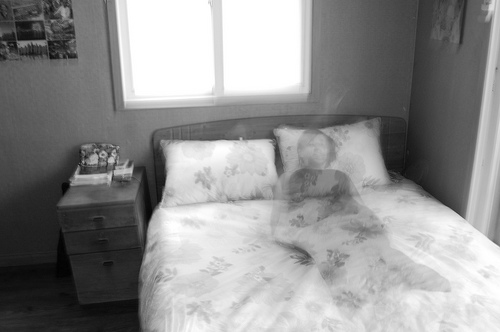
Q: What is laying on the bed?
A: It looks like a ghost of a woman.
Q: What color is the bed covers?
A: White.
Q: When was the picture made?
A: During the day.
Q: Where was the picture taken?
A: In the bedroom.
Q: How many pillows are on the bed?
A: Two.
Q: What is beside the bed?
A: A night stand.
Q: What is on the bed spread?
A: Flowers.